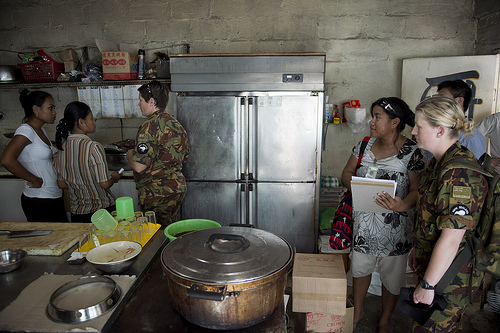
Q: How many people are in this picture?
A: Seven.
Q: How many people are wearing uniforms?
A: Two.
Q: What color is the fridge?
A: Silver.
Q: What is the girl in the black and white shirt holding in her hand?
A: A tablet of paper.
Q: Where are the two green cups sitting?
A: On top of the glass cups.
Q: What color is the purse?
A: Red and black.